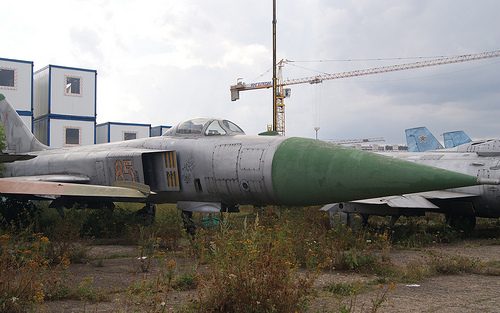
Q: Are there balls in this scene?
A: No, there are no balls.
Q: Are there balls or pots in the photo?
A: No, there are no balls or pots.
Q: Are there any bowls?
A: No, there are no bowls.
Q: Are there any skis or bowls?
A: No, there are no bowls or skis.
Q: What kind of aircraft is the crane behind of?
A: The crane is behind the plane.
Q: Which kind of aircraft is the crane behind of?
A: The crane is behind the plane.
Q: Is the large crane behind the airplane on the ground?
A: Yes, the crane is behind the plane.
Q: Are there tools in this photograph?
A: No, there are no tools.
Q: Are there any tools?
A: No, there are no tools.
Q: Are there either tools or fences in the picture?
A: No, there are no tools or fences.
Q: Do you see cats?
A: No, there are no cats.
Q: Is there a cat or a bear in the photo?
A: No, there are no cats or bears.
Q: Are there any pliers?
A: No, there are no pliers.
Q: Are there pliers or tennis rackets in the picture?
A: No, there are no pliers or tennis rackets.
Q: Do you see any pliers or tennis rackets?
A: No, there are no pliers or tennis rackets.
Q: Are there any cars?
A: No, there are no cars.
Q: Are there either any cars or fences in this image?
A: No, there are no cars or fences.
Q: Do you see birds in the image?
A: No, there are no birds.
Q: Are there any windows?
A: Yes, there is a window.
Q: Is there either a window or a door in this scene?
A: Yes, there is a window.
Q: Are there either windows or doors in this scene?
A: Yes, there is a window.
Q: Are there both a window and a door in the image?
A: No, there is a window but no doors.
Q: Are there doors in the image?
A: No, there are no doors.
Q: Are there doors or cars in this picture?
A: No, there are no doors or cars.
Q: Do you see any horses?
A: No, there are no horses.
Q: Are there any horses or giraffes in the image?
A: No, there are no horses or giraffes.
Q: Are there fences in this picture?
A: No, there are no fences.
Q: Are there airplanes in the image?
A: Yes, there is an airplane.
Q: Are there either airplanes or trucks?
A: Yes, there is an airplane.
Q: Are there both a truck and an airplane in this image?
A: No, there is an airplane but no trucks.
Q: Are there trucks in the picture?
A: No, there are no trucks.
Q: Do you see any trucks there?
A: No, there are no trucks.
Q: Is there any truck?
A: No, there are no trucks.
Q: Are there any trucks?
A: No, there are no trucks.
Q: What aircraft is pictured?
A: The aircraft is an airplane.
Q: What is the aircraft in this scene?
A: The aircraft is an airplane.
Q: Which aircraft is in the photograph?
A: The aircraft is an airplane.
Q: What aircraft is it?
A: The aircraft is an airplane.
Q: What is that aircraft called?
A: That is an airplane.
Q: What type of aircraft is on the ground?
A: The aircraft is an airplane.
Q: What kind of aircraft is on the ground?
A: The aircraft is an airplane.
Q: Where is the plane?
A: The plane is on the ground.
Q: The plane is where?
A: The plane is on the ground.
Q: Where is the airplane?
A: The plane is on the ground.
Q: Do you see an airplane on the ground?
A: Yes, there is an airplane on the ground.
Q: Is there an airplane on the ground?
A: Yes, there is an airplane on the ground.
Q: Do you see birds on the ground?
A: No, there is an airplane on the ground.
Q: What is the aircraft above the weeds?
A: The aircraft is an airplane.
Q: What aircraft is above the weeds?
A: The aircraft is an airplane.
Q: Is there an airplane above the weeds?
A: Yes, there is an airplane above the weeds.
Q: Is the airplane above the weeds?
A: Yes, the airplane is above the weeds.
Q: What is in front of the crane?
A: The airplane is in front of the crane.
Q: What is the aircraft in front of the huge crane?
A: The aircraft is an airplane.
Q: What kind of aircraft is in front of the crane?
A: The aircraft is an airplane.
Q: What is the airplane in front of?
A: The airplane is in front of the crane.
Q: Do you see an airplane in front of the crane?
A: Yes, there is an airplane in front of the crane.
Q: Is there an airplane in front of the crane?
A: Yes, there is an airplane in front of the crane.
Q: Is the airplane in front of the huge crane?
A: Yes, the airplane is in front of the crane.